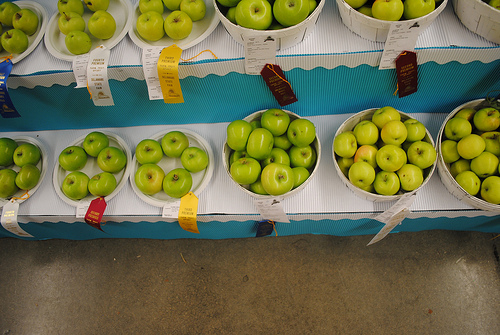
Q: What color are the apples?
A: Green.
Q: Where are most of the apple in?
A: Baskets.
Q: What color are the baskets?
A: White.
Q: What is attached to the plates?
A: Ribbons.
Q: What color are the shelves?
A: White and Blue.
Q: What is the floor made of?
A: Concrete.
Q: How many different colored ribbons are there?
A: 4.